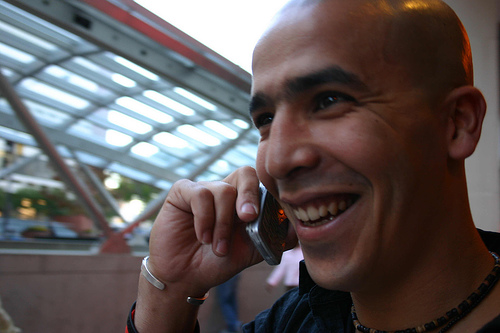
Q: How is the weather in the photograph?
A: It is clear.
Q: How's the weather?
A: It is clear.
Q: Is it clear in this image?
A: Yes, it is clear.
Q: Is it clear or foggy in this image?
A: It is clear.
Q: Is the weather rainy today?
A: No, it is clear.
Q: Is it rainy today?
A: No, it is clear.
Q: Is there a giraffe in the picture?
A: No, there are no giraffes.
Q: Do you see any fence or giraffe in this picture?
A: No, there are no giraffes or fences.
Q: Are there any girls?
A: No, there are no girls.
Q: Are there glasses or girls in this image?
A: No, there are no girls or glasses.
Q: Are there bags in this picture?
A: No, there are no bags.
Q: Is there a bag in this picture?
A: No, there are no bags.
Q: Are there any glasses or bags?
A: No, there are no bags or glasses.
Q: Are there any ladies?
A: No, there are no ladies.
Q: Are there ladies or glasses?
A: No, there are no ladies or glasses.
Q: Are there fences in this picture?
A: No, there are no fences.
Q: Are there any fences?
A: No, there are no fences.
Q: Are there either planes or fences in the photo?
A: No, there are no fences or planes.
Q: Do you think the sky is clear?
A: Yes, the sky is clear.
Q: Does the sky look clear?
A: Yes, the sky is clear.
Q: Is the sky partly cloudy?
A: No, the sky is clear.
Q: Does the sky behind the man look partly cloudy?
A: No, the sky is clear.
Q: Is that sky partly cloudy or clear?
A: The sky is clear.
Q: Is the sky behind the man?
A: Yes, the sky is behind the man.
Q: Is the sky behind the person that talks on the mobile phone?
A: Yes, the sky is behind the man.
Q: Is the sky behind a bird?
A: No, the sky is behind the man.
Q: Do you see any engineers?
A: No, there are no engineers.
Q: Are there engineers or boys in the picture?
A: No, there are no engineers or boys.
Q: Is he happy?
A: Yes, the man is happy.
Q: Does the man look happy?
A: Yes, the man is happy.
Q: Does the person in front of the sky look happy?
A: Yes, the man is happy.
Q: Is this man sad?
A: No, the man is happy.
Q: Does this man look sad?
A: No, the man is happy.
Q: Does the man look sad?
A: No, the man is happy.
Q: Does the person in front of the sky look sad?
A: No, the man is happy.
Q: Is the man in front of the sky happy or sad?
A: The man is happy.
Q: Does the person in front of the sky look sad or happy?
A: The man is happy.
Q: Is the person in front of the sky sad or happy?
A: The man is happy.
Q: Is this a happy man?
A: Yes, this is a happy man.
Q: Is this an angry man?
A: No, this is a happy man.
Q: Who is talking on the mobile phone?
A: The man is talking on the mobile phone.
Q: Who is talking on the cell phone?
A: The man is talking on the mobile phone.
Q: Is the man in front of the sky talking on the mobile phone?
A: Yes, the man is talking on the mobile phone.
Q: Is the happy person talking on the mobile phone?
A: Yes, the man is talking on the mobile phone.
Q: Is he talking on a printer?
A: No, the man is talking on the mobile phone.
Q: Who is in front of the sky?
A: The man is in front of the sky.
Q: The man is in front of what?
A: The man is in front of the sky.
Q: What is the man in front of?
A: The man is in front of the sky.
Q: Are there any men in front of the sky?
A: Yes, there is a man in front of the sky.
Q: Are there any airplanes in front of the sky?
A: No, there is a man in front of the sky.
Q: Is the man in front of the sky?
A: Yes, the man is in front of the sky.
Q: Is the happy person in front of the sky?
A: Yes, the man is in front of the sky.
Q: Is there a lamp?
A: No, there are no lamps.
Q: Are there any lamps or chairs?
A: No, there are no lamps or chairs.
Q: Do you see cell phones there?
A: Yes, there is a cell phone.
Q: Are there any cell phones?
A: Yes, there is a cell phone.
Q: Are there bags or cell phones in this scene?
A: Yes, there is a cell phone.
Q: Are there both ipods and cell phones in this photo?
A: No, there is a cell phone but no ipods.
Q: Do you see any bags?
A: No, there are no bags.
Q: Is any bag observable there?
A: No, there are no bags.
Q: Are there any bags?
A: No, there are no bags.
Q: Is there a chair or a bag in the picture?
A: No, there are no bags or chairs.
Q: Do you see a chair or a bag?
A: No, there are no bags or chairs.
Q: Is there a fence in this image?
A: No, there are no fences.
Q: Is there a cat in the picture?
A: No, there are no cats.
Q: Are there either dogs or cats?
A: No, there are no cats or dogs.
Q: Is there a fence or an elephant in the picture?
A: No, there are no fences or elephants.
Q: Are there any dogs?
A: No, there are no dogs.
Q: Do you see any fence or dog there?
A: No, there are no dogs or fences.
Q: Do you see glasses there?
A: No, there are no glasses.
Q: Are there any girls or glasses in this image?
A: No, there are no glasses or girls.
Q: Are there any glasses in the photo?
A: No, there are no glasses.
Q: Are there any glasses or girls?
A: No, there are no glasses or girls.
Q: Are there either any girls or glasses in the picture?
A: No, there are no glasses or girls.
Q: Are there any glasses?
A: No, there are no glasses.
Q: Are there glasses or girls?
A: No, there are no glasses or girls.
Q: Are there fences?
A: No, there are no fences.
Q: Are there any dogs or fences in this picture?
A: No, there are no fences or dogs.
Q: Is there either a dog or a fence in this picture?
A: No, there are no fences or dogs.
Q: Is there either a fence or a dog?
A: No, there are no fences or dogs.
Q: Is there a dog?
A: No, there are no dogs.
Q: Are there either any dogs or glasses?
A: No, there are no dogs or glasses.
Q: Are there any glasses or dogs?
A: No, there are no dogs or glasses.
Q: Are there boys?
A: No, there are no boys.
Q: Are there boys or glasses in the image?
A: No, there are no boys or glasses.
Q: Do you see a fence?
A: No, there are no fences.